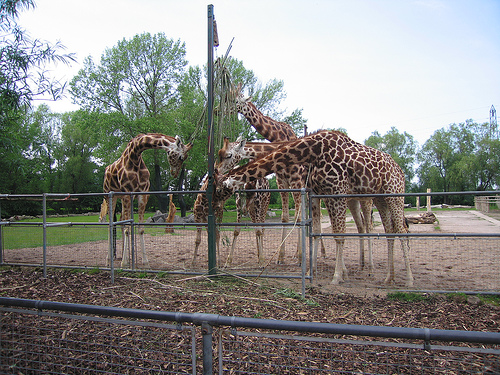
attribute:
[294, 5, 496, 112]
sky — cloudy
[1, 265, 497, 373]
ground — part 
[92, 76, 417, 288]
herd — giraffe, captive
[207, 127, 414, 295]
giraffe — captive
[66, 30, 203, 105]
leaves — green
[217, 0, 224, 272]
pole — metal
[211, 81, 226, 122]
food — giraffe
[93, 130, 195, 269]
giraffe — captive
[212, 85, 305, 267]
giraffe — captive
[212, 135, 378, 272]
giraffe — captive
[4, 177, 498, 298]
pen — holding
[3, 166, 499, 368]
pen — holding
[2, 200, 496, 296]
dirt — ground